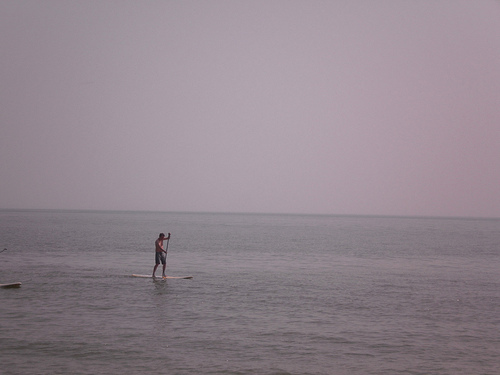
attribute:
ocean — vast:
[19, 209, 496, 372]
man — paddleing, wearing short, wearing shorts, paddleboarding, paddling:
[147, 224, 175, 280]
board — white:
[132, 267, 195, 283]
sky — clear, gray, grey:
[15, 11, 491, 103]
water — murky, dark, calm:
[7, 252, 98, 337]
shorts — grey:
[153, 251, 172, 267]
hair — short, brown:
[160, 232, 164, 238]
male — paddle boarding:
[137, 231, 188, 281]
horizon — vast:
[4, 200, 499, 255]